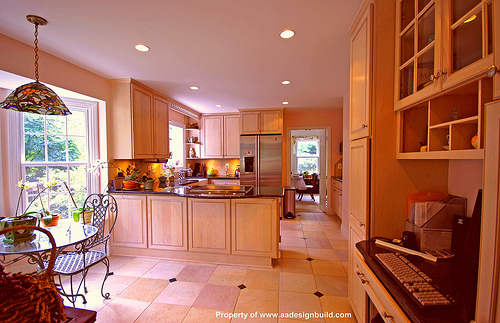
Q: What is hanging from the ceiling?
A: Lamp.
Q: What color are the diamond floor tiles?
A: Black.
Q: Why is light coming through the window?
A: It's daytime.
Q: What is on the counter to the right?
A: Keyboard.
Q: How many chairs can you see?
A: Two.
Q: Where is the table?
A: To the left.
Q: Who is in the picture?
A: No one.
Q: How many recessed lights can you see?
A: Six.